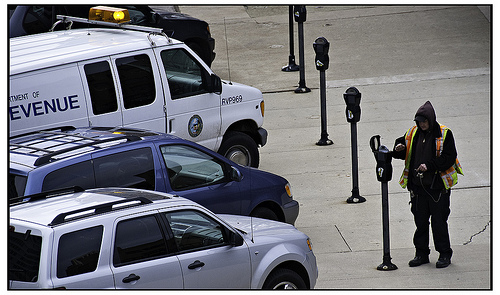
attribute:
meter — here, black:
[369, 134, 397, 271]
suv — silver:
[10, 187, 318, 292]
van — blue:
[8, 126, 299, 227]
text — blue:
[8, 90, 80, 118]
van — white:
[8, 6, 267, 170]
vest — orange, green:
[398, 124, 465, 189]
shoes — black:
[437, 253, 453, 268]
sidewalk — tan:
[150, 5, 492, 290]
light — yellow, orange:
[88, 6, 132, 23]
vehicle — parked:
[9, 186, 319, 292]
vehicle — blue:
[9, 125, 300, 226]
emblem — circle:
[187, 114, 203, 138]